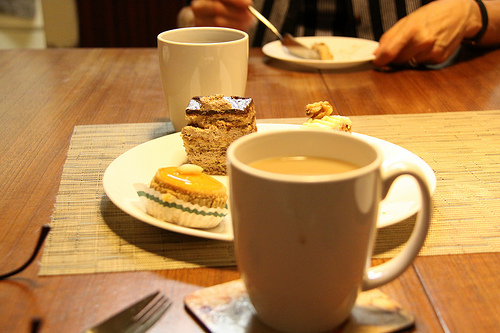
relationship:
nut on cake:
[306, 89, 353, 119] [176, 68, 277, 149]